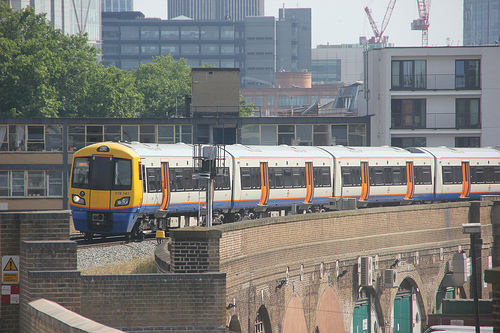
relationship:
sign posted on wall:
[0, 254, 20, 284] [0, 210, 20, 330]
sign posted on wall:
[1, 284, 20, 303] [0, 210, 20, 330]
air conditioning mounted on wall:
[382, 267, 399, 289] [219, 200, 485, 330]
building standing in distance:
[3, 0, 103, 61] [2, 2, 484, 145]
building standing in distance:
[103, 0, 133, 13] [2, 2, 484, 145]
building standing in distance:
[102, 10, 243, 85] [2, 2, 484, 145]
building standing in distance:
[165, 1, 264, 19] [2, 2, 484, 145]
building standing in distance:
[276, 4, 311, 71] [2, 2, 484, 145]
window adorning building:
[390, 60, 425, 89] [362, 39, 484, 146]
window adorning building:
[390, 95, 403, 128] [362, 39, 484, 146]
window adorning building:
[390, 100, 426, 128] [362, 39, 484, 146]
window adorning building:
[455, 96, 471, 127] [362, 39, 484, 146]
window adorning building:
[413, 60, 426, 89] [362, 39, 484, 146]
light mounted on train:
[70, 194, 81, 203] [63, 136, 480, 242]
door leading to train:
[303, 162, 313, 202] [63, 136, 480, 242]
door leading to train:
[303, 159, 313, 202] [63, 136, 480, 242]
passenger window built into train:
[239, 167, 265, 187] [63, 136, 480, 242]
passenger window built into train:
[220, 164, 231, 188] [63, 136, 480, 242]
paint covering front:
[70, 202, 141, 235] [64, 139, 141, 234]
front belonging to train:
[64, 139, 141, 234] [63, 136, 480, 242]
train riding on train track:
[63, 136, 480, 242] [75, 233, 156, 247]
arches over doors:
[318, 252, 432, 330] [352, 284, 414, 330]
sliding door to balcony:
[392, 60, 424, 86] [387, 57, 487, 93]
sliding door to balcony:
[392, 60, 425, 90] [387, 57, 487, 93]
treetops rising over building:
[4, 6, 185, 113] [7, 115, 368, 205]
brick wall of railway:
[19, 210, 224, 324] [16, 203, 498, 330]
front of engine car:
[61, 137, 140, 234] [56, 137, 235, 228]